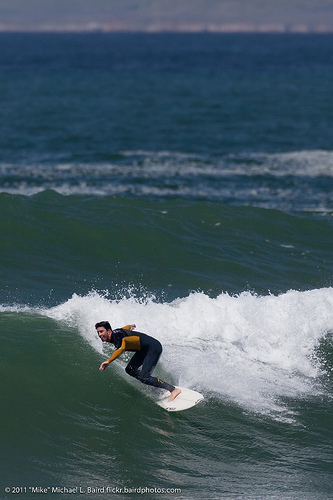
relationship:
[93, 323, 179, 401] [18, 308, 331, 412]
man surfing wave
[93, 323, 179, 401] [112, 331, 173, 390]
man wearing wet suit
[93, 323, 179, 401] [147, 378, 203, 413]
man standing on surfboard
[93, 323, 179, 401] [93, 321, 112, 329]
man with hair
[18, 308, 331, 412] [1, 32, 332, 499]
wave over water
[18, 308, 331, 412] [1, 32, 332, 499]
wave on water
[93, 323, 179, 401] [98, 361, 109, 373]
man has hand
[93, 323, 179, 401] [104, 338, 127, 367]
man has arm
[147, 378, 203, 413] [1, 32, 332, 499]
surfboard in water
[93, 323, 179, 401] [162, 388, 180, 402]
man has feet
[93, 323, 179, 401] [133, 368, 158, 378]
man has knee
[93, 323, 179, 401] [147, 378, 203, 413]
man on surfboard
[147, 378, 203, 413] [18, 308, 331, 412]
surfboard on wave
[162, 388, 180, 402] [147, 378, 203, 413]
feet on surfboard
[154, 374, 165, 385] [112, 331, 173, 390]
logo on wet suit